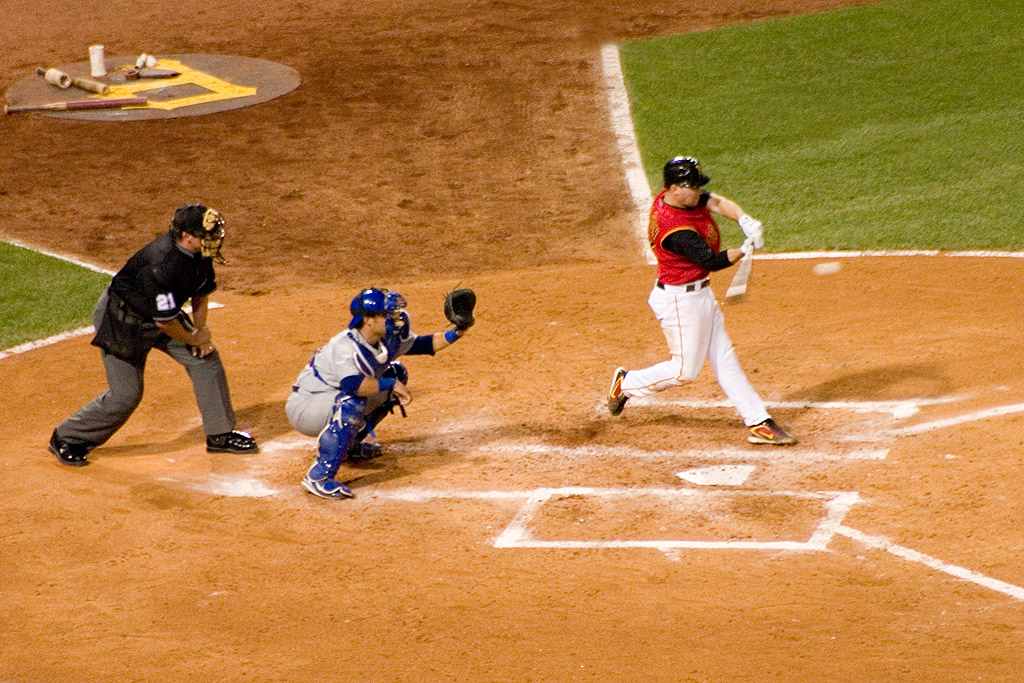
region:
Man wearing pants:
[618, 279, 777, 428]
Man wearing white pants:
[610, 275, 772, 430]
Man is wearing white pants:
[605, 273, 782, 426]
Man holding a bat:
[716, 216, 765, 312]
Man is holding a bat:
[721, 216, 764, 309]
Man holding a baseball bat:
[721, 219, 772, 306]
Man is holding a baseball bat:
[712, 209, 771, 307]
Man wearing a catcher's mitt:
[437, 277, 496, 336]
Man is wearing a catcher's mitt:
[438, 282, 486, 331]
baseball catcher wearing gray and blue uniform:
[283, 282, 480, 499]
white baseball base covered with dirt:
[681, 456, 758, 491]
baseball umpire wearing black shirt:
[49, 197, 265, 467]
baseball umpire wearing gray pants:
[47, 202, 257, 468]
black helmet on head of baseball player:
[663, 150, 715, 193]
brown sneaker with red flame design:
[744, 417, 803, 447]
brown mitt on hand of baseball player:
[442, 282, 481, 328]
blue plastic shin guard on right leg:
[306, 392, 370, 482]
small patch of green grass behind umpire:
[2, 235, 228, 360]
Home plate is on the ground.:
[666, 448, 774, 490]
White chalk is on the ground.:
[211, 386, 1022, 596]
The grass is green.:
[619, 4, 1022, 248]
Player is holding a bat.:
[604, 148, 797, 471]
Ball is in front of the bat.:
[803, 247, 851, 286]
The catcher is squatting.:
[272, 265, 484, 499]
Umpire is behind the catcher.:
[49, 198, 266, 477]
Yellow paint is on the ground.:
[60, 54, 270, 112]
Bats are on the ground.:
[6, 59, 155, 133]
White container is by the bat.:
[75, 38, 121, 89]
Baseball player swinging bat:
[607, 152, 800, 447]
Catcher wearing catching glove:
[288, 287, 478, 502]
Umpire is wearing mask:
[49, 206, 256, 462]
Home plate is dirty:
[674, 458, 758, 488]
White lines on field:
[1, 0, 1022, 681]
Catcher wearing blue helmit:
[279, 285, 476, 498]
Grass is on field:
[1, 3, 1020, 373]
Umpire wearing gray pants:
[49, 200, 256, 464]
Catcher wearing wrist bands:
[285, 285, 469, 500]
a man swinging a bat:
[629, 167, 892, 471]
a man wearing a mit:
[214, 276, 475, 483]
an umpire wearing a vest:
[130, 179, 244, 351]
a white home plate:
[692, 429, 804, 534]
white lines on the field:
[873, 216, 962, 275]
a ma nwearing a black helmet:
[616, 122, 689, 237]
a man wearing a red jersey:
[632, 159, 700, 315]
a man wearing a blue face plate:
[238, 230, 425, 437]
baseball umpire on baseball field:
[47, 195, 259, 475]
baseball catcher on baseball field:
[271, 262, 490, 501]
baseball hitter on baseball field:
[575, 136, 797, 479]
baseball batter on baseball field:
[598, 141, 791, 451]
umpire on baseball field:
[29, 198, 273, 468]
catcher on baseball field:
[274, 262, 475, 496]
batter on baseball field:
[560, 113, 795, 467]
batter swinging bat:
[590, 136, 821, 466]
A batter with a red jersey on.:
[596, 143, 811, 485]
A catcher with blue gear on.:
[275, 263, 494, 511]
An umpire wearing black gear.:
[35, 177, 255, 488]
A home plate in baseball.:
[628, 417, 796, 548]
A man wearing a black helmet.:
[648, 142, 726, 216]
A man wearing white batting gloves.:
[726, 200, 772, 265]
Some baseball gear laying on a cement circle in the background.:
[15, 25, 194, 137]